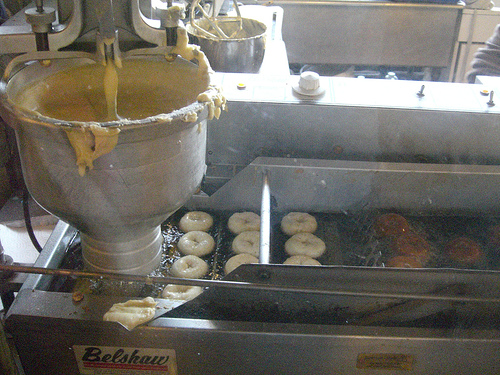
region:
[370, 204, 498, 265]
The donuts that are fried.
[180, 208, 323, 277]
The donuts that are not fried.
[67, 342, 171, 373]
The name of the machine is belshaw.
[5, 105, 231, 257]
The silver mixing bowl.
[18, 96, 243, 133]
The batter in the mixing bowl.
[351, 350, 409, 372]
The yellow sticker on the machine.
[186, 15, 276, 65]
The mixing bowl in the background.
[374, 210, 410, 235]
This is a doughnut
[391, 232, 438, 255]
This is a doughnut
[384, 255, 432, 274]
This is a doughnut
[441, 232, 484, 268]
This is a doughnut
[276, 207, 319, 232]
A raw doughnut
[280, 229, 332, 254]
A raw doughnut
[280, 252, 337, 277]
A raw doughnut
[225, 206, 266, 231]
A raw doughnut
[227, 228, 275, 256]
A raw doughnut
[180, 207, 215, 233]
White doughnut in the fryer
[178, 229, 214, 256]
White doughnut in the fryer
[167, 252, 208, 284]
White doughnut in the fryer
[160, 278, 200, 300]
White doughnut in the fryer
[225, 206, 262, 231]
White doughnut in the fryer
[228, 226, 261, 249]
White doughnut in the fryer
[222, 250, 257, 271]
White doughnut in the fryer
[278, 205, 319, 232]
White doughnut in the fryer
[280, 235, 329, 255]
White doughnut in the fryer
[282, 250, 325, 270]
White doughnut in the fryer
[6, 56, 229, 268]
this is a dough mixer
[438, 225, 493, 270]
the doughnut is in the oven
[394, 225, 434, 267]
the doughnut is in the oven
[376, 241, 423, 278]
the doughnut is in the oven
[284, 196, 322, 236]
the doughnut is in the oven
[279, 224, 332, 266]
the doughnut is in the oven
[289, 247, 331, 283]
the doughnut is in the oven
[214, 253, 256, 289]
the doughnut is in the oven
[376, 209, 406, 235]
doughnut frying in oil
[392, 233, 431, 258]
doughnut frying in oil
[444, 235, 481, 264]
doughnut frying in oil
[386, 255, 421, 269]
doughnut frying in oil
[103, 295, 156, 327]
glob of uncooked batter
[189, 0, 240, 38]
large metal pastry mixer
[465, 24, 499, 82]
sleeve of a brown sweater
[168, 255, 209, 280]
uncooked doughnut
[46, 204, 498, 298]
vat of boiling oil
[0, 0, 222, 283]
doughnut batter dispenser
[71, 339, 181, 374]
company name on a sticker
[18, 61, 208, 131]
batter in a funnel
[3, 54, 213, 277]
silver metal batter container